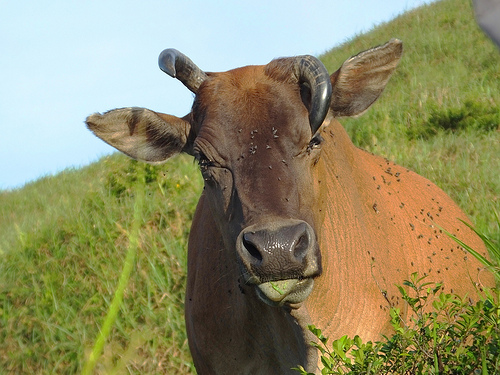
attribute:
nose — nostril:
[222, 225, 313, 267]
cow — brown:
[84, 31, 444, 170]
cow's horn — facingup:
[293, 47, 335, 145]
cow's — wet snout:
[258, 227, 297, 289]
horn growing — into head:
[283, 33, 345, 156]